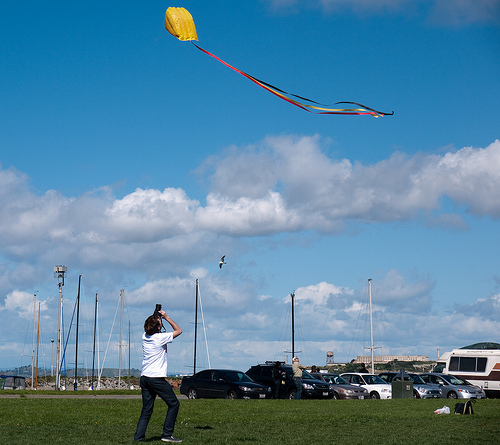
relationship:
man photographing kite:
[132, 307, 184, 445] [163, 8, 199, 46]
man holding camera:
[132, 307, 184, 442] [151, 302, 163, 320]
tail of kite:
[192, 45, 393, 120] [163, 8, 199, 46]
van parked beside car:
[245, 364, 335, 400] [178, 369, 272, 397]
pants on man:
[132, 375, 180, 440] [132, 307, 184, 442]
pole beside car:
[369, 276, 374, 376] [334, 371, 392, 400]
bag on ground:
[453, 400, 473, 415] [1, 388, 498, 444]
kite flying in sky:
[163, 8, 199, 46] [1, 1, 499, 366]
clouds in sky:
[1, 132, 500, 375] [1, 1, 499, 366]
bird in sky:
[217, 253, 228, 270] [1, 1, 499, 366]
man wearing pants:
[132, 307, 184, 442] [132, 375, 180, 440]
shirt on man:
[139, 329, 174, 381] [132, 307, 184, 442]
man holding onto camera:
[132, 307, 184, 442] [151, 302, 163, 320]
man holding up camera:
[132, 307, 184, 442] [151, 302, 163, 320]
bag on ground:
[436, 404, 451, 416] [1, 388, 498, 444]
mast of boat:
[30, 300, 41, 389] [1, 373, 30, 389]